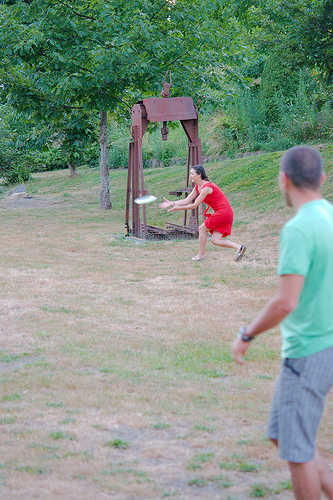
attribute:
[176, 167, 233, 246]
woman — catching, white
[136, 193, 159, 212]
frisbee — flying, white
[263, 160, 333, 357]
man — looking, watching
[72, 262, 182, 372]
grass — dying, green, brown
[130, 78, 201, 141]
well — metal, brown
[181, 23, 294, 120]
trees — close, far, green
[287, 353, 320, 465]
shorts — blue, striped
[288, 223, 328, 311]
shirt — green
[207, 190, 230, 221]
dress — red